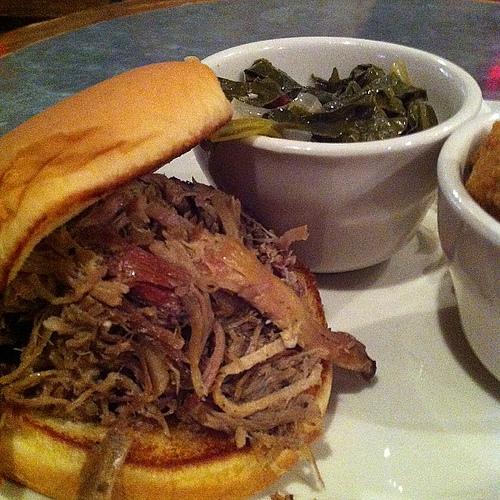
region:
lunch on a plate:
[3, 30, 488, 499]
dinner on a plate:
[2, 52, 499, 497]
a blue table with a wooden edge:
[32, 1, 499, 51]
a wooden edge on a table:
[4, 11, 113, 52]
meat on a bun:
[4, 68, 336, 495]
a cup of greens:
[220, 43, 466, 208]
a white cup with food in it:
[201, 34, 465, 289]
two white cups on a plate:
[199, 31, 499, 378]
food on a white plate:
[17, 43, 492, 497]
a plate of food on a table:
[12, 4, 499, 499]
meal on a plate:
[7, 4, 497, 497]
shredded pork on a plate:
[71, 223, 303, 428]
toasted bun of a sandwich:
[14, 425, 259, 482]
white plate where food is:
[371, 288, 441, 498]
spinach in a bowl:
[249, 58, 418, 131]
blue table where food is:
[56, 16, 188, 67]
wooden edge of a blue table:
[8, 19, 78, 54]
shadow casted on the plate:
[393, 298, 465, 436]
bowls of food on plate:
[203, 19, 495, 373]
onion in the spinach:
[274, 85, 328, 110]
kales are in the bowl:
[256, 59, 420, 142]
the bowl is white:
[216, 35, 448, 279]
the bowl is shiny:
[218, 33, 440, 281]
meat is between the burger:
[105, 205, 285, 364]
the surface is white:
[384, 358, 454, 467]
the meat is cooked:
[88, 247, 250, 400]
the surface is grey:
[101, 25, 210, 55]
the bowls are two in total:
[219, 45, 499, 364]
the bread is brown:
[1, 77, 226, 245]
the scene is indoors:
[6, 5, 498, 485]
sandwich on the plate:
[5, 46, 351, 498]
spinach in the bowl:
[192, 39, 471, 290]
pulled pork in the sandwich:
[58, 215, 305, 430]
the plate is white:
[352, 305, 492, 498]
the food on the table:
[11, 13, 493, 499]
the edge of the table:
[7, 0, 103, 52]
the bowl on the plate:
[193, 38, 463, 280]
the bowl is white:
[185, 43, 475, 288]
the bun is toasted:
[3, 57, 228, 244]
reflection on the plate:
[365, 442, 427, 481]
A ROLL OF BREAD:
[88, 111, 175, 157]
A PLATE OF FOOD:
[53, 229, 260, 396]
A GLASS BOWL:
[308, 144, 408, 243]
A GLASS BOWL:
[463, 224, 483, 281]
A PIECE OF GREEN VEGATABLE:
[406, 99, 435, 127]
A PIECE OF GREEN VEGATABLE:
[243, 49, 284, 94]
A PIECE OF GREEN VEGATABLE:
[318, 89, 368, 129]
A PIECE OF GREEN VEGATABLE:
[330, 63, 342, 92]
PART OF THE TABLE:
[374, 422, 406, 454]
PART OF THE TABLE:
[370, 282, 408, 336]